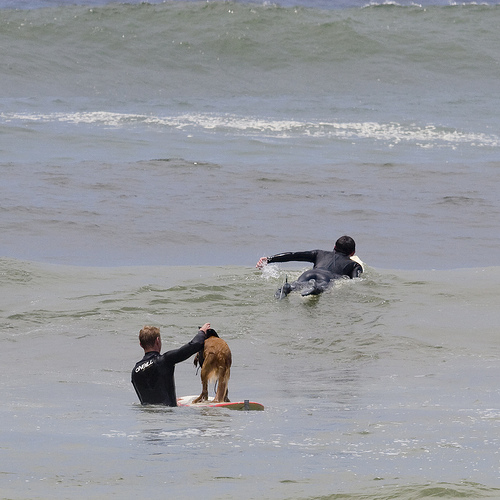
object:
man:
[131, 322, 210, 409]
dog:
[193, 323, 231, 405]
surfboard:
[178, 395, 265, 412]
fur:
[205, 337, 232, 364]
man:
[256, 232, 369, 299]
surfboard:
[351, 254, 365, 270]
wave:
[4, 110, 500, 151]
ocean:
[2, 2, 498, 499]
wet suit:
[131, 330, 205, 407]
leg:
[194, 360, 213, 405]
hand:
[199, 322, 210, 332]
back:
[315, 251, 352, 276]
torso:
[135, 355, 177, 406]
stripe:
[210, 401, 264, 409]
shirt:
[267, 251, 362, 279]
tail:
[215, 354, 226, 404]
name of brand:
[132, 357, 156, 375]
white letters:
[134, 365, 141, 373]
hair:
[333, 235, 355, 256]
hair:
[138, 325, 160, 348]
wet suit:
[268, 251, 362, 295]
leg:
[215, 363, 231, 402]